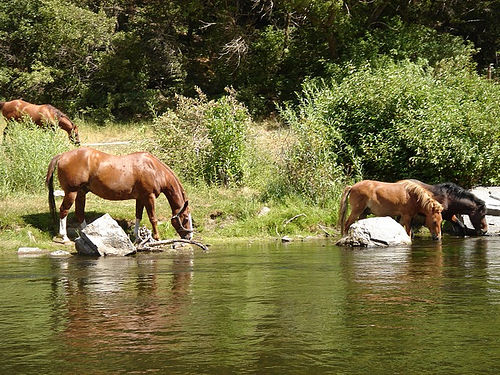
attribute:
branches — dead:
[131, 225, 209, 253]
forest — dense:
[0, 0, 497, 232]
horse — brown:
[45, 146, 194, 241]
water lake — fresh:
[122, 265, 412, 374]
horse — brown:
[353, 177, 441, 232]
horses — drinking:
[333, 173, 493, 240]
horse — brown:
[40, 147, 192, 252]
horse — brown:
[338, 179, 440, 238]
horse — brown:
[430, 181, 485, 232]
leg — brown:
[50, 190, 81, 223]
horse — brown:
[2, 89, 91, 151]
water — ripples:
[0, 242, 485, 372]